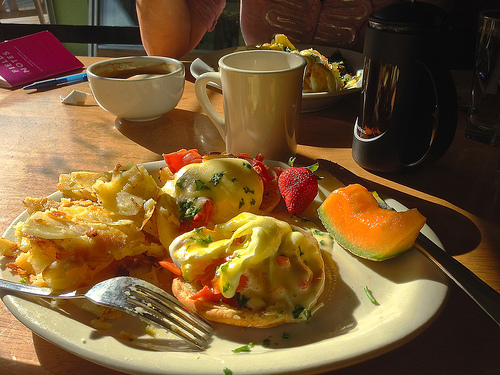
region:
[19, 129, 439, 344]
A breakfast on a plate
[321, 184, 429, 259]
A piece of canteloupe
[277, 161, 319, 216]
A strawberry on the plate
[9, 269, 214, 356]
A fork for the breakfast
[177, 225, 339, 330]
Eggs benedict on the plate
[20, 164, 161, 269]
Hash brown potatoes on the plate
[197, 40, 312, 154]
A cup of coffee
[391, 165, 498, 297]
A knife for the meal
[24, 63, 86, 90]
A pen on the table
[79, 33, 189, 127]
A second coffee on the table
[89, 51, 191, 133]
Bowl with brown liquid.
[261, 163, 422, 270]
Fruit on plate.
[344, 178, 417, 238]
Melon with bite eaten from it.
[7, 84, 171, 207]
Shadows on wooden table.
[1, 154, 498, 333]
Utensils and food on white plate.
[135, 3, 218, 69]
Elbow of white person.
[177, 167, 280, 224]
Parsley bits on food.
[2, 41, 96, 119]
Wadded paper, pen and small book.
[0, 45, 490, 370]
Table with bowl, plates, cups,utensils, food and other items.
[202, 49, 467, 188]
Black hot cup, white china cup, standing beside each other.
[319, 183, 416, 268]
Slice of cantaloupe with bite.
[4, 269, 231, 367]
Dirty fork, face down.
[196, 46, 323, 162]
White mug on table.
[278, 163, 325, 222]
Strawberry on plate.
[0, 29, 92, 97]
Purple book by blue pen.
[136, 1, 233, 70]
Elbow on table.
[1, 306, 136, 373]
Shadow near plate.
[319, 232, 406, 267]
Cantaloupe rind under cantaloupe.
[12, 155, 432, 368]
Plate with fork, knife and breakfast on it.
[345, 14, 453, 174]
Tall, silver and black cup.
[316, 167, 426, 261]
A slice of cantaloupe sitting on a plate.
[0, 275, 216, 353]
A silver fork resting on a plate.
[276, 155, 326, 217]
One red strawberry.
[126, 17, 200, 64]
One elbow resting on the table.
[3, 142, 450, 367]
A plate of delicious food.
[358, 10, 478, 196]
A coffee maker.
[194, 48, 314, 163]
A large white coffee cup.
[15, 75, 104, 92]
One writing pen.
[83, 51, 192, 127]
A coffee cup filled with coffee.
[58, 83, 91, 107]
A small piece of folded paper.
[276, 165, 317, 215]
"Plump red strawberry"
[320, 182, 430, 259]
"Juicy orange cantelope"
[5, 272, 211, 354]
"Silver fork on a plate"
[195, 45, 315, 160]
"White coffee cup"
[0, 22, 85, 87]
"Small pink notebook"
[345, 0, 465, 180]
"Shiny black coffee carafe"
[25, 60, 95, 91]
"Blue pen with black lid"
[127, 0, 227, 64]
"Woman's elbow on the table"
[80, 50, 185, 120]
"Small white half full bowl"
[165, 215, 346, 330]
"Yellow eggs on bread"